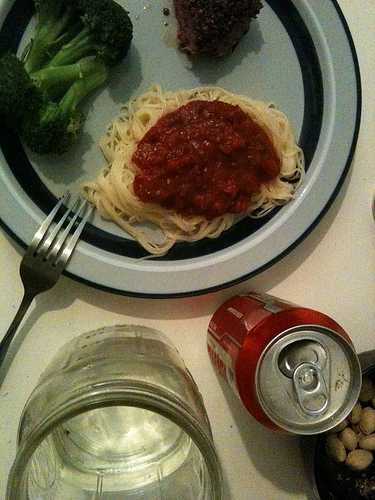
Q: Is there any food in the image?
A: Yes, there is food.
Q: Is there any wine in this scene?
A: No, there is no wine.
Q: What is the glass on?
A: The glass is on the table.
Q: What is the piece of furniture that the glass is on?
A: The piece of furniture is a table.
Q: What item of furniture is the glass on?
A: The glass is on the table.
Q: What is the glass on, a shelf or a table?
A: The glass is on a table.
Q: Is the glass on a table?
A: Yes, the glass is on a table.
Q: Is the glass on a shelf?
A: No, the glass is on a table.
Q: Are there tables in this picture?
A: Yes, there is a table.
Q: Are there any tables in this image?
A: Yes, there is a table.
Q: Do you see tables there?
A: Yes, there is a table.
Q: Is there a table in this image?
A: Yes, there is a table.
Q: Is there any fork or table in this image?
A: Yes, there is a table.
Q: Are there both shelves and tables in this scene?
A: No, there is a table but no shelves.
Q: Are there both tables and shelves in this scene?
A: No, there is a table but no shelves.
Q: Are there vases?
A: No, there are no vases.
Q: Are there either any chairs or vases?
A: No, there are no vases or chairs.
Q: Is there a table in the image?
A: Yes, there is a table.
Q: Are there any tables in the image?
A: Yes, there is a table.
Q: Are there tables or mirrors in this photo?
A: Yes, there is a table.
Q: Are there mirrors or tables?
A: Yes, there is a table.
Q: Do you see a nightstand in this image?
A: No, there are no nightstands.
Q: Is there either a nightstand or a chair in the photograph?
A: No, there are no nightstands or chairs.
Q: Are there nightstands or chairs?
A: No, there are no nightstands or chairs.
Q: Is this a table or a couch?
A: This is a table.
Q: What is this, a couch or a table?
A: This is a table.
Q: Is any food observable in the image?
A: Yes, there is food.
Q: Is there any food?
A: Yes, there is food.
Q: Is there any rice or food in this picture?
A: Yes, there is food.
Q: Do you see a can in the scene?
A: Yes, there is a can.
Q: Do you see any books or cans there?
A: Yes, there is a can.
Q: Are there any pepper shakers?
A: No, there are no pepper shakers.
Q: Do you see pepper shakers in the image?
A: No, there are no pepper shakers.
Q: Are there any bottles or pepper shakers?
A: No, there are no pepper shakers or bottles.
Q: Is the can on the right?
A: Yes, the can is on the right of the image.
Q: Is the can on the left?
A: No, the can is on the right of the image.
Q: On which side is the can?
A: The can is on the right of the image.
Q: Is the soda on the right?
A: Yes, the soda is on the right of the image.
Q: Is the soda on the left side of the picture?
A: No, the soda is on the right of the image.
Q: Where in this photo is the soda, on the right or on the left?
A: The soda is on the right of the image.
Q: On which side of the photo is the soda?
A: The soda is on the right of the image.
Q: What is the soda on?
A: The soda is on the table.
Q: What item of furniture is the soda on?
A: The soda is on the table.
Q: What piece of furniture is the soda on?
A: The soda is on the table.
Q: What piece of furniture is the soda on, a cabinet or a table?
A: The soda is on a table.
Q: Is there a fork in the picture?
A: Yes, there is a fork.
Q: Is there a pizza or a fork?
A: Yes, there is a fork.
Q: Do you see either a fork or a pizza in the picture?
A: Yes, there is a fork.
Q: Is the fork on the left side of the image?
A: Yes, the fork is on the left of the image.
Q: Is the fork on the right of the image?
A: No, the fork is on the left of the image.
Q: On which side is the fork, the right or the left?
A: The fork is on the left of the image.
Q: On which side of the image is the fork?
A: The fork is on the left of the image.